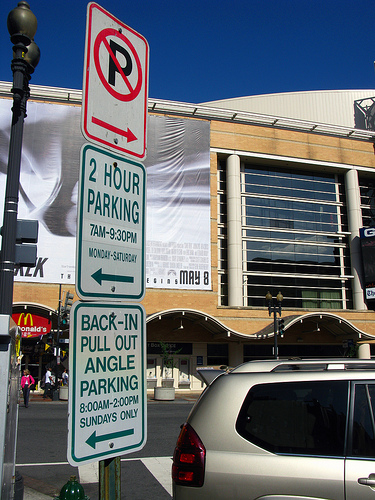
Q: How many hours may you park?
A: 2.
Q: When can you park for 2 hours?
A: 7 AM to 9:30 PM.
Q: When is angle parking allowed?
A: 8:00 AM to 2:00 PM on Sundays.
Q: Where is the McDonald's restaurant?
A: Background of lower left corner.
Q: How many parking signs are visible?
A: 3.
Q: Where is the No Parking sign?
A: Top of the signpost.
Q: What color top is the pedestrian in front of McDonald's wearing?
A: Pink.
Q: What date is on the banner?
A: May 8.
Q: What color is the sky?
A: Blue.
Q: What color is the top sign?
A: White.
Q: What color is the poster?
A: Gray.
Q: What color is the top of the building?
A: White.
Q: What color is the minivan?
A: Gray.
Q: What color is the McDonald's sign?
A: Red.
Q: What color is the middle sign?
A: White.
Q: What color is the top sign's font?
A: Red.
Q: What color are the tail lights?
A: Red.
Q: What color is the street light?
A: Black.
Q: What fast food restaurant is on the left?
A: McDonalds.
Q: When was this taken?
A: During the day.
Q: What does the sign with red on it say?
A: No parking.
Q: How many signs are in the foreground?
A: Three.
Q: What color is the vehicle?
A: Silver.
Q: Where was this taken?
A: On a sidewalk.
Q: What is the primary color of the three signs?
A: White.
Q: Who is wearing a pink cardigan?
A: The woman standing in front of McDonald's.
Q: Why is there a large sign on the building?
A: To advertise Star Trek.